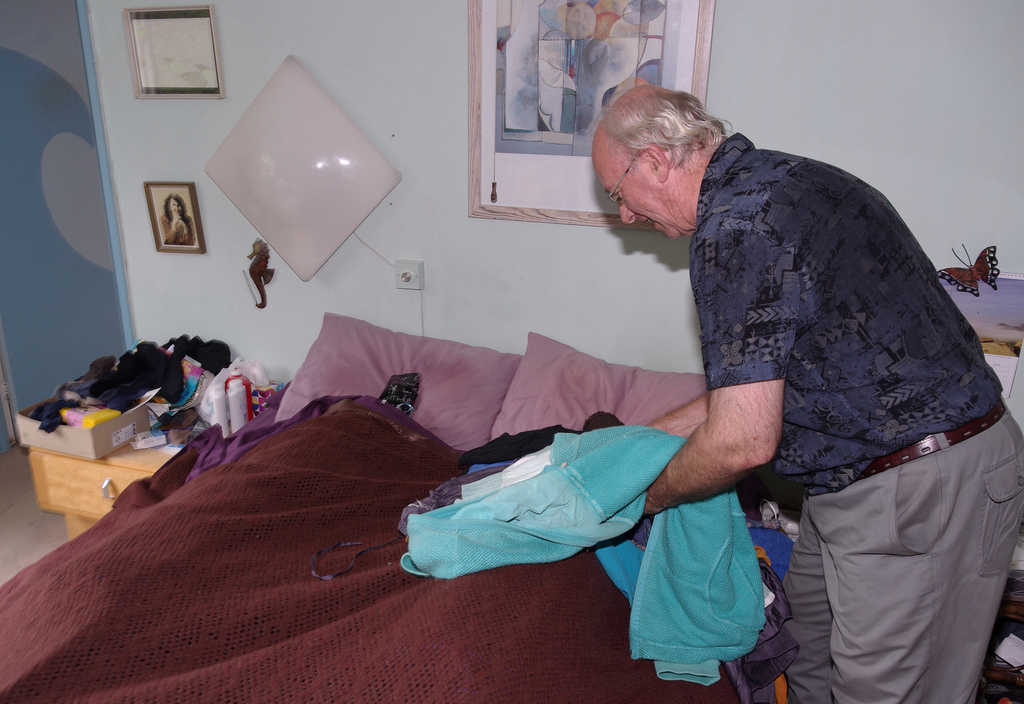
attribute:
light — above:
[198, 57, 418, 274]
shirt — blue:
[658, 152, 1019, 472]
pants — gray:
[766, 446, 1011, 691]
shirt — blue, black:
[658, 133, 994, 478]